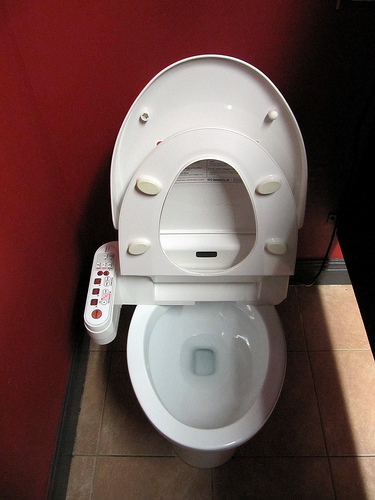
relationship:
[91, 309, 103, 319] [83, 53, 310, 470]
button on side of toilet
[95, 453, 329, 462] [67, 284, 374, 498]
line on floor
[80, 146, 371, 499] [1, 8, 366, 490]
shadow in stall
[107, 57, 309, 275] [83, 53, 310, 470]
lid of toilet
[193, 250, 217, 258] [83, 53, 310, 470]
sensor on toilet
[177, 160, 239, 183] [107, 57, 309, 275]
text on underside of lid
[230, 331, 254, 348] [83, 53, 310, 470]
reflection in toilet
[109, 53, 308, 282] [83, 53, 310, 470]
cover of toilet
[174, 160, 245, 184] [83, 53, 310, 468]
sticker on back of toliet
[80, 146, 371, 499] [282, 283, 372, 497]
shadow on floor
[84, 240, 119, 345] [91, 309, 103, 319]
toilet arm has button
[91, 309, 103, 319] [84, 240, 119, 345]
button on toilet arm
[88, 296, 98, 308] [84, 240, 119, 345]
button on toilet arm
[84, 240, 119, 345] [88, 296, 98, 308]
toilet arm has button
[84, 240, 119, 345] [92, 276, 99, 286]
toilet arm has button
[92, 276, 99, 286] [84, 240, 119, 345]
button on toilet arm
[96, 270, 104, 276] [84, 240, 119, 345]
button on toilet arm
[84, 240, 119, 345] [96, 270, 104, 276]
toilet arm has button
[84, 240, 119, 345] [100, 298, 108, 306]
toilet arm has button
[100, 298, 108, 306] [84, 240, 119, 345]
button on toilet arm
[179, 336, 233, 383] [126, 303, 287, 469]
water in bottom of toilet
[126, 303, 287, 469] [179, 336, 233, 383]
toilet has water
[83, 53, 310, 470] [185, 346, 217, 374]
toilet has water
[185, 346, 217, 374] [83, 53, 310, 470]
water in bottom of toilet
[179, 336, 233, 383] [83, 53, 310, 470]
water in bottom of toilet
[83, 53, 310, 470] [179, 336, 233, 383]
toilet has water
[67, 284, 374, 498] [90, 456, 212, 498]
floor has tile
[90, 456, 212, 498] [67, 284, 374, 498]
tile on floor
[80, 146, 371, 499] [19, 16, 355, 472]
shadow from bathroom stall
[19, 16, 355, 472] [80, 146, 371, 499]
bathroom stall has shadow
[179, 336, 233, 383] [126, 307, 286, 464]
water in toilet bowl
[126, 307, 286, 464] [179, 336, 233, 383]
toilet bowl has water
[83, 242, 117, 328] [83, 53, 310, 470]
control panel on toilet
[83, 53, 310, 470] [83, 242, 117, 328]
toilet has control panel